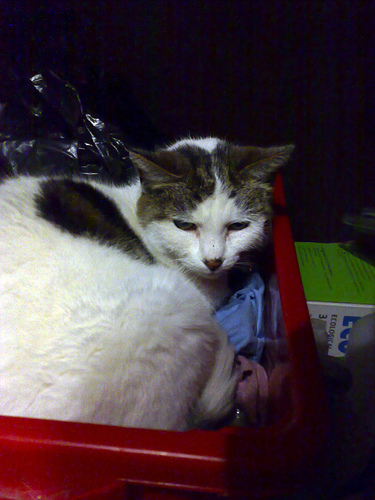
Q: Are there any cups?
A: No, there are no cups.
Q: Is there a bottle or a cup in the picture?
A: No, there are no cups or bottles.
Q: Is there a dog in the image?
A: No, there are no dogs.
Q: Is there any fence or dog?
A: No, there are no dogs or fences.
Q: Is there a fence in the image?
A: No, there are no fences.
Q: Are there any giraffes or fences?
A: No, there are no fences or giraffes.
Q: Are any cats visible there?
A: Yes, there is a cat.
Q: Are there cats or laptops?
A: Yes, there is a cat.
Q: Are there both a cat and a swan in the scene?
A: No, there is a cat but no swans.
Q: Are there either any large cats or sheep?
A: Yes, there is a large cat.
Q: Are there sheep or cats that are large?
A: Yes, the cat is large.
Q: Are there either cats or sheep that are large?
A: Yes, the cat is large.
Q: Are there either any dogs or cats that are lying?
A: Yes, the cat is lying.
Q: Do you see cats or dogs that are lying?
A: Yes, the cat is lying.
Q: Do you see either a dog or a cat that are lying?
A: Yes, the cat is lying.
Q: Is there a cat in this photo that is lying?
A: Yes, there is a cat that is lying.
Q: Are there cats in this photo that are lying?
A: Yes, there is a cat that is lying.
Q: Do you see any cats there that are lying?
A: Yes, there is a cat that is lying.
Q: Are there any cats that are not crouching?
A: Yes, there is a cat that is lying.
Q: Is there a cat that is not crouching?
A: Yes, there is a cat that is lying.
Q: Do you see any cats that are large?
A: Yes, there is a large cat.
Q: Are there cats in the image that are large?
A: Yes, there is a cat that is large.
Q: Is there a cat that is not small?
A: Yes, there is a large cat.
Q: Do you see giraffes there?
A: No, there are no giraffes.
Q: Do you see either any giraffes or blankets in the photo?
A: No, there are no giraffes or blankets.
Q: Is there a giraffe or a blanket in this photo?
A: No, there are no giraffes or blankets.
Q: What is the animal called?
A: The animal is a cat.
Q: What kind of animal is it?
A: The animal is a cat.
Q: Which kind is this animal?
A: This is a cat.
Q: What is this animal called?
A: This is a cat.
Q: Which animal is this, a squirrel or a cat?
A: This is a cat.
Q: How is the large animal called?
A: The animal is a cat.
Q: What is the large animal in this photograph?
A: The animal is a cat.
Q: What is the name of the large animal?
A: The animal is a cat.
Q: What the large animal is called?
A: The animal is a cat.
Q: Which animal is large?
A: The animal is a cat.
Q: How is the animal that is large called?
A: The animal is a cat.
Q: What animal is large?
A: The animal is a cat.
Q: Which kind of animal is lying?
A: The animal is a cat.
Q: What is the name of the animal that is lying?
A: The animal is a cat.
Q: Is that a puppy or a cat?
A: That is a cat.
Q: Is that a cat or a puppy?
A: That is a cat.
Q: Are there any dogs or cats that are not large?
A: No, there is a cat but it is large.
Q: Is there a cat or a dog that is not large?
A: No, there is a cat but it is large.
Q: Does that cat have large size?
A: Yes, the cat is large.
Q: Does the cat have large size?
A: Yes, the cat is large.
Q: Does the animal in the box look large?
A: Yes, the cat is large.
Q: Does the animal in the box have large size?
A: Yes, the cat is large.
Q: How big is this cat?
A: The cat is large.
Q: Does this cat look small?
A: No, the cat is large.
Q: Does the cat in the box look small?
A: No, the cat is large.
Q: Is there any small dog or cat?
A: No, there is a cat but it is large.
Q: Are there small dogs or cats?
A: No, there is a cat but it is large.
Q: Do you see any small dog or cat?
A: No, there is a cat but it is large.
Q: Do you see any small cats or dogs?
A: No, there is a cat but it is large.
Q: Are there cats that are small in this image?
A: No, there is a cat but it is large.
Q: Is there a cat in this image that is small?
A: No, there is a cat but it is large.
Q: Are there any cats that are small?
A: No, there is a cat but it is large.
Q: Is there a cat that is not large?
A: No, there is a cat but it is large.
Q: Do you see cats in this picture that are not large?
A: No, there is a cat but it is large.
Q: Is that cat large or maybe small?
A: The cat is large.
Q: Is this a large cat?
A: Yes, this is a large cat.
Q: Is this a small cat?
A: No, this is a large cat.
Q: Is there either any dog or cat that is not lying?
A: No, there is a cat but it is lying.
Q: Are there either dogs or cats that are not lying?
A: No, there is a cat but it is lying.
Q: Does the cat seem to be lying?
A: Yes, the cat is lying.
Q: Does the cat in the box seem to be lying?
A: Yes, the cat is lying.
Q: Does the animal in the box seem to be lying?
A: Yes, the cat is lying.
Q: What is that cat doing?
A: The cat is lying.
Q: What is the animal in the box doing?
A: The cat is lying.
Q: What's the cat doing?
A: The cat is lying.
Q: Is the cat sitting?
A: No, the cat is lying.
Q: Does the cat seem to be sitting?
A: No, the cat is lying.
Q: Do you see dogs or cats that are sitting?
A: No, there is a cat but it is lying.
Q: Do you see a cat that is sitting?
A: No, there is a cat but it is lying.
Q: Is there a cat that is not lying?
A: No, there is a cat but it is lying.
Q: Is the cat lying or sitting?
A: The cat is lying.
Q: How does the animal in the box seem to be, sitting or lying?
A: The cat is lying.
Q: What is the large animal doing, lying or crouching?
A: The cat is lying.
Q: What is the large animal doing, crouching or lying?
A: The cat is lying.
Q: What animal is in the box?
A: The cat is in the box.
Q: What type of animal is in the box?
A: The animal is a cat.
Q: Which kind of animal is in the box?
A: The animal is a cat.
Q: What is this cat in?
A: The cat is in the box.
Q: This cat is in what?
A: The cat is in the box.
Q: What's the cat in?
A: The cat is in the box.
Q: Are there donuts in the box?
A: No, there is a cat in the box.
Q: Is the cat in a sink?
A: No, the cat is in the box.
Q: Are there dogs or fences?
A: No, there are no fences or dogs.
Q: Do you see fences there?
A: No, there are no fences.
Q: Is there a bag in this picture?
A: Yes, there is a bag.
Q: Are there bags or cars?
A: Yes, there is a bag.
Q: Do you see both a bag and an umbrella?
A: No, there is a bag but no umbrellas.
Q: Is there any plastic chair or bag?
A: Yes, there is a plastic bag.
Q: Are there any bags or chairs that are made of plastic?
A: Yes, the bag is made of plastic.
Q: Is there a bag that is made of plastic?
A: Yes, there is a bag that is made of plastic.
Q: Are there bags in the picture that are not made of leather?
A: Yes, there is a bag that is made of plastic.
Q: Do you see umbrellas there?
A: No, there are no umbrellas.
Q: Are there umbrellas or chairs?
A: No, there are no umbrellas or chairs.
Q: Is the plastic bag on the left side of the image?
A: Yes, the bag is on the left of the image.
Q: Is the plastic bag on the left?
A: Yes, the bag is on the left of the image.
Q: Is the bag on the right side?
A: No, the bag is on the left of the image.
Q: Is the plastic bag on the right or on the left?
A: The bag is on the left of the image.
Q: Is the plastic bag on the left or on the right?
A: The bag is on the left of the image.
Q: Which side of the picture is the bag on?
A: The bag is on the left of the image.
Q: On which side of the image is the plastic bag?
A: The bag is on the left of the image.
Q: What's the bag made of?
A: The bag is made of plastic.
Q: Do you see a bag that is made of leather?
A: No, there is a bag but it is made of plastic.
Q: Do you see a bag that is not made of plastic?
A: No, there is a bag but it is made of plastic.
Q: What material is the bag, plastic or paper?
A: The bag is made of plastic.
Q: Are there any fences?
A: No, there are no fences.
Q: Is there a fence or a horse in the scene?
A: No, there are no fences or horses.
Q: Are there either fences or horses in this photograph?
A: No, there are no fences or horses.